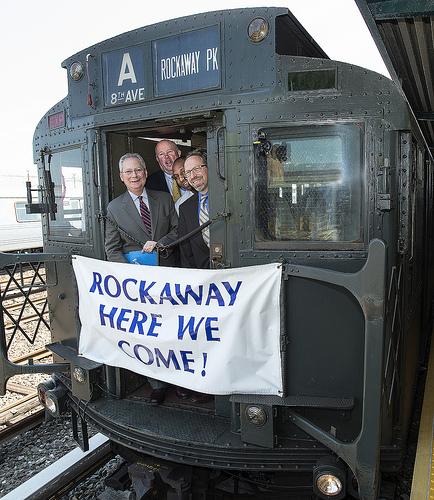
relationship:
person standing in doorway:
[101, 151, 180, 267] [100, 122, 221, 418]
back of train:
[30, 6, 399, 500] [24, 6, 433, 499]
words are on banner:
[86, 272, 244, 379] [69, 253, 287, 398]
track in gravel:
[1, 432, 111, 500] [0, 403, 123, 498]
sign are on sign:
[153, 23, 224, 100] [153, 23, 224, 100]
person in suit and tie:
[101, 151, 180, 267] [102, 188, 180, 267]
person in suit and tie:
[101, 151, 180, 267] [144, 173, 187, 202]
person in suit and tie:
[101, 151, 180, 267] [178, 195, 210, 266]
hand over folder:
[140, 241, 157, 253] [123, 249, 159, 267]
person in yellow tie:
[101, 151, 180, 267] [170, 173, 180, 202]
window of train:
[262, 125, 362, 241] [24, 6, 433, 499]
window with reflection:
[262, 125, 362, 241] [269, 165, 340, 236]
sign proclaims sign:
[153, 23, 224, 100] [153, 23, 224, 100]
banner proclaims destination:
[69, 253, 287, 398] [91, 271, 244, 306]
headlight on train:
[316, 469, 345, 497] [24, 6, 433, 499]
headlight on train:
[41, 393, 59, 419] [24, 6, 433, 499]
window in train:
[262, 125, 362, 241] [24, 6, 433, 499]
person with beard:
[101, 151, 180, 267] [191, 182, 209, 193]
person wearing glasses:
[101, 151, 180, 267] [182, 163, 207, 179]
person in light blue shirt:
[101, 151, 180, 267] [197, 190, 211, 219]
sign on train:
[153, 23, 224, 100] [24, 6, 433, 499]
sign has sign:
[153, 23, 224, 100] [153, 23, 224, 100]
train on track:
[24, 6, 433, 499] [1, 432, 111, 500]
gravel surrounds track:
[0, 403, 123, 498] [1, 432, 111, 500]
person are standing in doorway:
[101, 151, 180, 267] [100, 122, 221, 418]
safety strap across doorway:
[97, 211, 230, 251] [100, 122, 221, 418]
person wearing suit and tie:
[101, 151, 180, 267] [102, 188, 180, 267]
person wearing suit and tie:
[101, 151, 180, 267] [144, 173, 187, 202]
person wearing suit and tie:
[101, 151, 180, 267] [175, 186, 200, 215]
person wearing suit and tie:
[101, 151, 180, 267] [178, 195, 210, 266]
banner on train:
[69, 253, 287, 398] [24, 6, 433, 499]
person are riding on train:
[101, 151, 180, 267] [24, 6, 433, 499]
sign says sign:
[153, 23, 224, 100] [153, 23, 224, 100]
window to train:
[262, 125, 362, 241] [24, 6, 433, 499]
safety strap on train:
[97, 211, 230, 251] [24, 6, 433, 499]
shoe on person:
[147, 387, 167, 405] [101, 151, 180, 267]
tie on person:
[136, 196, 154, 236] [101, 151, 180, 267]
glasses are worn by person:
[182, 163, 207, 179] [101, 151, 180, 267]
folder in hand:
[123, 249, 159, 267] [140, 241, 157, 253]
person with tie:
[101, 151, 180, 267] [136, 196, 154, 236]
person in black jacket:
[101, 151, 180, 267] [178, 195, 209, 270]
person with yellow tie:
[101, 151, 180, 267] [170, 173, 180, 202]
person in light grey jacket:
[101, 151, 180, 267] [102, 188, 180, 265]